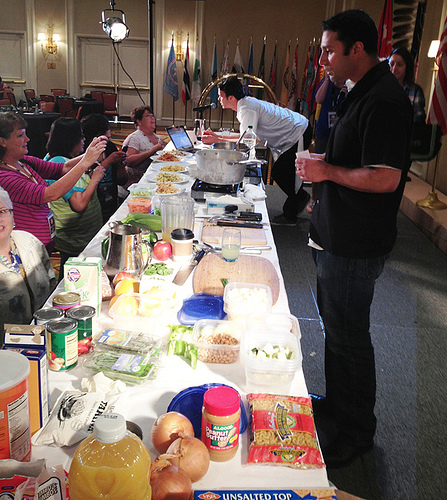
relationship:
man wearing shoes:
[293, 8, 411, 468] [312, 398, 376, 467]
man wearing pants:
[293, 8, 411, 468] [312, 243, 389, 438]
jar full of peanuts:
[203, 385, 242, 462] [201, 408, 243, 462]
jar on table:
[203, 385, 242, 462] [1, 131, 330, 499]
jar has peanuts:
[203, 385, 242, 462] [201, 408, 243, 462]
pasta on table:
[246, 393, 323, 470] [1, 131, 330, 499]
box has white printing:
[194, 488, 336, 499] [222, 492, 294, 500]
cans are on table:
[33, 291, 98, 373] [1, 131, 330, 499]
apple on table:
[154, 240, 172, 262] [1, 131, 330, 499]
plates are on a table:
[143, 148, 194, 197] [1, 131, 330, 499]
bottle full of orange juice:
[68, 411, 153, 499] [68, 413, 152, 499]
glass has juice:
[220, 225, 241, 263] [223, 245, 240, 260]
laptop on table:
[166, 125, 201, 154] [1, 131, 330, 499]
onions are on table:
[151, 410, 209, 499] [1, 131, 330, 499]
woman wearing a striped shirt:
[0, 112, 108, 255] [0, 153, 64, 252]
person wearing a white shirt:
[217, 76, 314, 225] [237, 96, 308, 162]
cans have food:
[33, 291, 98, 373] [33, 291, 99, 371]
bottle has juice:
[68, 411, 153, 499] [68, 413, 152, 499]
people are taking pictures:
[0, 8, 427, 498] [89, 135, 110, 185]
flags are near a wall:
[165, 30, 321, 128] [1, 1, 346, 129]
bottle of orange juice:
[68, 411, 153, 499] [68, 413, 152, 499]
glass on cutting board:
[220, 225, 241, 263] [192, 251, 280, 306]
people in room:
[0, 8, 427, 498] [4, 3, 446, 488]